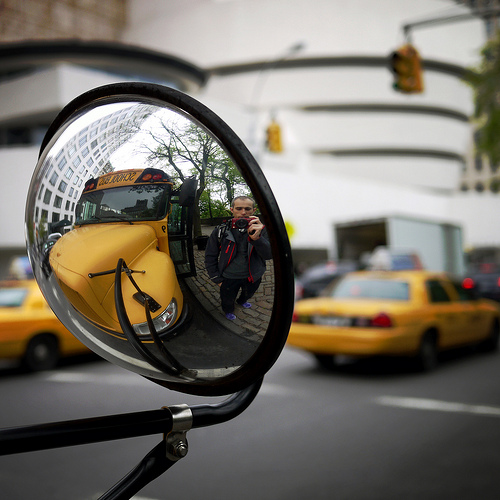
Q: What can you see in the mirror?
A: A school bus and a man.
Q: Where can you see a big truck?
A: When you pass the traffic lights on the left.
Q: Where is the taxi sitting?
A: In the road past the white line in street.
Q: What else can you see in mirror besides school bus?
A: A building on the left.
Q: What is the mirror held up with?
A: With black pole with silver around it.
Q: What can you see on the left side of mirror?
A: The back of a taxi cab.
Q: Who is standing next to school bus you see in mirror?
A: A man with a camera.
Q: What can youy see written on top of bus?
A: You can see words school bus.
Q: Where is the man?
A: In the reflection.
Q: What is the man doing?
A: Taking a picture.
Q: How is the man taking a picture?
A: With a camera.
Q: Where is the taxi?
A: On the raod.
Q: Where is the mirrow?
A: On a bus.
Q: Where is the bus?
A: By the man.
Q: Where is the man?
A: On the sidewalk.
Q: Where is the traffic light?
A: Above the taxi.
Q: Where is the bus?
A: On the road.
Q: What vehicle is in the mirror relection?
A: Bus.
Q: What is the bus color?
A: Yellow.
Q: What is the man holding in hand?
A: Camera.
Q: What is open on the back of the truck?
A: Door.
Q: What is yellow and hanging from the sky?
A: Traffic signal.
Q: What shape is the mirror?
A: Circle.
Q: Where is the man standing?
A: On sidewalk.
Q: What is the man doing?
A: Taking pictures.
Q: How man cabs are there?
A: Two.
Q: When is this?
A: Daytime.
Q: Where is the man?
A: In the mirror.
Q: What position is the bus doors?
A: Open.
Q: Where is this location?
A: City street.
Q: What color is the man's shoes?
A: Blue.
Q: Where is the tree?
A: In back of the bus.